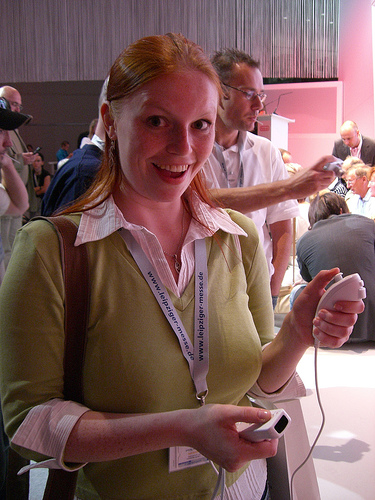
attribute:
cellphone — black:
[31, 144, 42, 155]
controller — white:
[304, 256, 366, 362]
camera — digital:
[319, 153, 349, 183]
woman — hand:
[6, 17, 373, 460]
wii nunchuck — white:
[212, 271, 365, 498]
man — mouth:
[197, 38, 308, 293]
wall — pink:
[2, 3, 373, 212]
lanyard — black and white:
[115, 222, 210, 471]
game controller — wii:
[287, 246, 361, 381]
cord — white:
[288, 338, 325, 498]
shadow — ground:
[304, 431, 373, 469]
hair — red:
[128, 48, 145, 77]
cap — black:
[2, 98, 31, 131]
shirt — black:
[3, 178, 313, 498]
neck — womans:
[98, 162, 226, 348]